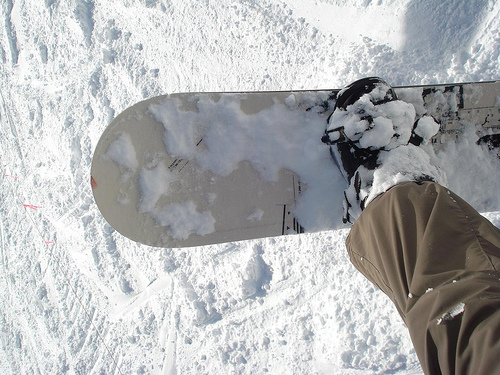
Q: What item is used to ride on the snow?
A: A snowboard.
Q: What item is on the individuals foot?
A: A shoe.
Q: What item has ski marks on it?
A: The snow.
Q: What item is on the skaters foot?
A: A snow board.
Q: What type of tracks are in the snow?
A: Snowboard tracks.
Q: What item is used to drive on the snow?
A: A snowboard.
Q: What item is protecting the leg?
A: A pant.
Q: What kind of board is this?
A: A snowboard.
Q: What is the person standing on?
A: A snowboard.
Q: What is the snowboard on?
A: Snow.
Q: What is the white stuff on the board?
A: Snow.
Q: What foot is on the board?
A: The left foot.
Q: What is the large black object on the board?
A: A boot.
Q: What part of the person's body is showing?
A: The left leg.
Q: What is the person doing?
A: Snowboarding.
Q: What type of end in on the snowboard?
A: Rounded edge.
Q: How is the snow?
A: White.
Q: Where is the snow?
A: Ground.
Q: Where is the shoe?
A: On board.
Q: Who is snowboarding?
A: The person.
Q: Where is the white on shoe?
A: Top.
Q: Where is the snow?
A: Board.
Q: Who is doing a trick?
A: The person.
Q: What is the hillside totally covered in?
A: Snow.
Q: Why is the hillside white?
A: It is covered with snow.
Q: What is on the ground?
A: Snow.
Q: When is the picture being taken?
A: Daytime.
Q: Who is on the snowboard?
A: A snowboarder.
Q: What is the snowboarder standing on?
A: A snowboard.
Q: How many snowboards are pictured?
A: One.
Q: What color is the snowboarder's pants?
A: Brown.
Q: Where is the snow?
A: Under the board.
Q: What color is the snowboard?
A: White and black.